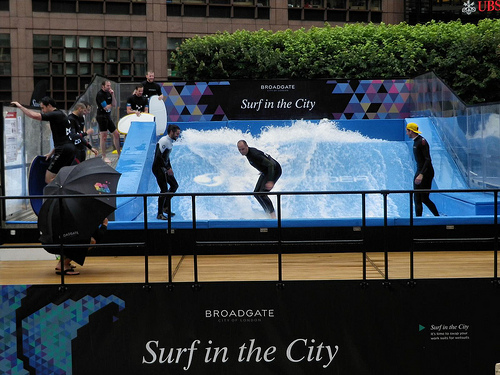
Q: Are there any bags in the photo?
A: No, there are no bags.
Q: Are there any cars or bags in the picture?
A: No, there are no bags or cars.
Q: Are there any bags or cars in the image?
A: No, there are no bags or cars.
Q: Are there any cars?
A: No, there are no cars.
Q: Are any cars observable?
A: No, there are no cars.